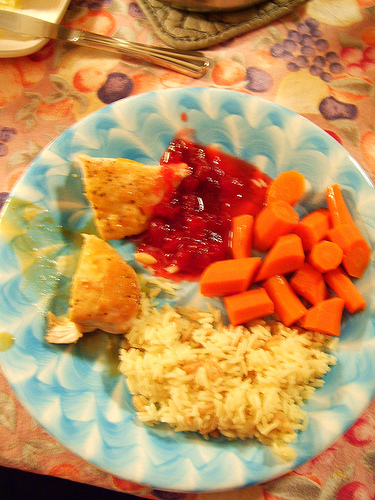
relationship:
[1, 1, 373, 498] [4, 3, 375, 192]
tablecloth has print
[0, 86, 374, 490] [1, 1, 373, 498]
plate on tablecloth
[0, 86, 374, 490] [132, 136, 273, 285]
plate under cherries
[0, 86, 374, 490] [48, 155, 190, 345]
plate under chicken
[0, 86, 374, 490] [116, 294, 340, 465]
plate under rice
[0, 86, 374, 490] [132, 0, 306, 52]
plate b potholder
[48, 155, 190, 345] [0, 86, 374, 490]
chicken on plate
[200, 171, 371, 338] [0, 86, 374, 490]
carrots are on plate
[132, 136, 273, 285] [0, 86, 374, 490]
cherries are on plate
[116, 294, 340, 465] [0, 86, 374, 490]
rice on plate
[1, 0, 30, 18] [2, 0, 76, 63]
butter in a dish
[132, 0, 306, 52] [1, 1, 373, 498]
potholder on tablecloth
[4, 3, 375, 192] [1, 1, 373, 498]
print on tablecloth